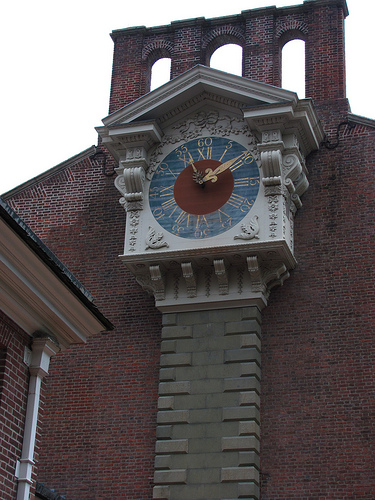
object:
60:
[198, 137, 213, 147]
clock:
[148, 137, 260, 239]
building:
[0, 8, 373, 498]